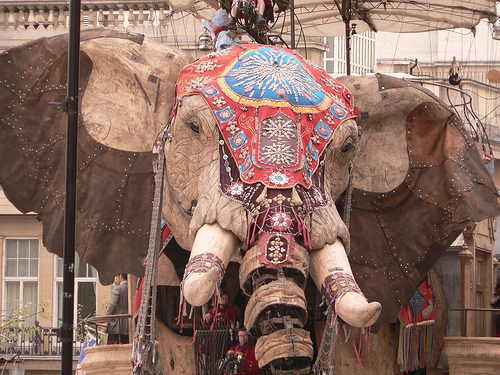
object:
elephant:
[1, 27, 500, 370]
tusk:
[181, 224, 241, 307]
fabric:
[175, 41, 363, 190]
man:
[103, 271, 129, 345]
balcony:
[79, 314, 136, 375]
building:
[0, 0, 500, 375]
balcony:
[0, 1, 174, 33]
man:
[200, 293, 238, 356]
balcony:
[0, 326, 77, 357]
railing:
[1, 320, 62, 355]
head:
[1, 29, 500, 335]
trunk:
[237, 235, 316, 374]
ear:
[0, 27, 195, 286]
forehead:
[178, 43, 363, 116]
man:
[190, 7, 243, 51]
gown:
[200, 11, 240, 52]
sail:
[271, 0, 499, 36]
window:
[4, 237, 40, 347]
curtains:
[6, 238, 36, 341]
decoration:
[319, 269, 367, 313]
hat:
[163, 42, 360, 264]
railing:
[448, 307, 499, 313]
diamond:
[272, 193, 286, 205]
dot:
[5, 51, 8, 54]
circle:
[224, 48, 325, 108]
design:
[223, 49, 324, 108]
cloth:
[177, 43, 357, 188]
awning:
[266, 1, 499, 34]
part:
[273, 315, 299, 329]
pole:
[344, 18, 352, 79]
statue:
[1, 26, 500, 375]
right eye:
[187, 121, 200, 134]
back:
[197, 44, 335, 77]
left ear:
[334, 73, 500, 334]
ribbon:
[192, 305, 200, 346]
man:
[226, 327, 257, 374]